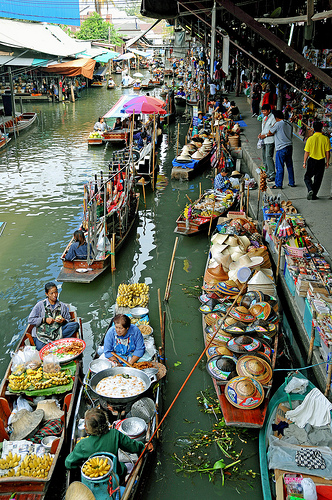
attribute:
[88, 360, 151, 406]
bowl — metal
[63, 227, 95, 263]
woman — young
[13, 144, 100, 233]
water — murky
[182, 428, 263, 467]
leaves — green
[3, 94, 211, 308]
water — murky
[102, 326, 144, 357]
shirt — blue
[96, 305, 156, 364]
hoodie — light, blue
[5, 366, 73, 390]
bananas — yellow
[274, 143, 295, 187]
jeans — blue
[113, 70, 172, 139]
umbrellas — rainbow colored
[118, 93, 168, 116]
umbrellas — large, red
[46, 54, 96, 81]
covering — orange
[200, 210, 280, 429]
boat — full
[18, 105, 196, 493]
water — dirty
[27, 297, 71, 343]
shirt — green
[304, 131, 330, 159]
shirt — yellow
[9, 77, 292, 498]
water — murky